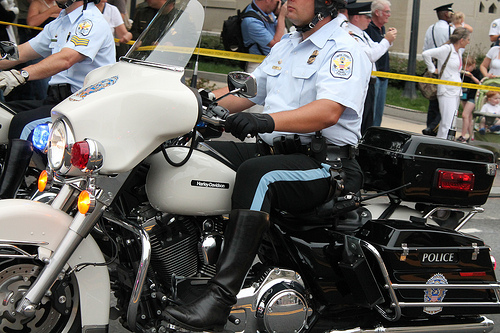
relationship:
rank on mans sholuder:
[68, 34, 89, 48] [61, 10, 102, 60]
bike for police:
[0, 0, 497, 333] [419, 244, 456, 269]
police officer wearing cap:
[425, 2, 452, 133] [433, 2, 451, 11]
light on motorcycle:
[430, 163, 476, 193] [46, 64, 441, 319]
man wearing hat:
[342, 1, 396, 142] [348, 2, 371, 20]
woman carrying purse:
[421, 26, 473, 139] [413, 49, 450, 102]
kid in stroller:
[475, 87, 496, 128] [473, 69, 496, 139]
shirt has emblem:
[33, 6, 124, 91] [65, 7, 97, 49]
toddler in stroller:
[487, 89, 499, 112] [469, 72, 499, 157]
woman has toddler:
[478, 45, 498, 77] [487, 89, 499, 112]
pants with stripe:
[190, 141, 367, 235] [247, 155, 339, 209]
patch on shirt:
[68, 18, 92, 46] [29, 2, 116, 93]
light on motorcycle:
[28, 104, 64, 167] [5, 3, 497, 331]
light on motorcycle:
[70, 140, 97, 167] [5, 3, 497, 331]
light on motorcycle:
[47, 113, 77, 175] [5, 3, 497, 331]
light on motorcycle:
[31, 122, 50, 156] [5, 3, 497, 331]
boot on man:
[166, 205, 271, 332] [156, 0, 372, 333]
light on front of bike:
[39, 113, 76, 180] [0, 27, 487, 331]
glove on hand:
[225, 112, 280, 138] [222, 110, 277, 142]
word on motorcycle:
[409, 251, 464, 272] [5, 3, 497, 331]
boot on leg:
[156, 209, 272, 333] [195, 156, 359, 278]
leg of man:
[195, 156, 359, 278] [156, 1, 371, 328]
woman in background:
[421, 27, 472, 139] [249, 0, 499, 135]